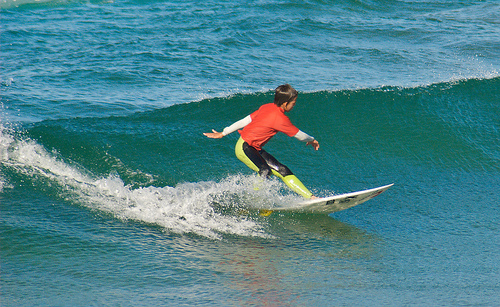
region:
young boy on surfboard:
[208, 63, 330, 215]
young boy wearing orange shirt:
[188, 62, 332, 211]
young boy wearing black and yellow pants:
[191, 67, 328, 209]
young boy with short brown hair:
[191, 60, 334, 212]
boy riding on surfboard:
[184, 67, 399, 222]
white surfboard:
[215, 177, 411, 214]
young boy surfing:
[167, 63, 409, 218]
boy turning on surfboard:
[187, 73, 406, 223]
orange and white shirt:
[221, 90, 311, 155]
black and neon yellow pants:
[228, 133, 323, 211]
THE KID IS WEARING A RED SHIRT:
[241, 97, 308, 157]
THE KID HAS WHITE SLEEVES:
[220, 110, 314, 151]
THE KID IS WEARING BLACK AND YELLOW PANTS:
[217, 135, 333, 205]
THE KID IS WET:
[190, 64, 351, 204]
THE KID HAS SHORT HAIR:
[271, 76, 297, 116]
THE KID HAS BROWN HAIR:
[268, 80, 300, 111]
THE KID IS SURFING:
[195, 80, 336, 212]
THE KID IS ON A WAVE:
[15, 66, 497, 221]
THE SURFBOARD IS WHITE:
[256, 178, 396, 222]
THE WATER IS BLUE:
[1, 1, 498, 302]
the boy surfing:
[202, 71, 327, 200]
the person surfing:
[205, 75, 326, 200]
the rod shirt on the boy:
[237, 104, 293, 150]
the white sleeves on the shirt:
[215, 114, 250, 137]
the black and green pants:
[229, 132, 324, 203]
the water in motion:
[12, 131, 241, 239]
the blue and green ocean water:
[397, 99, 497, 284]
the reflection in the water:
[217, 237, 291, 304]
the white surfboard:
[252, 175, 395, 219]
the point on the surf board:
[366, 179, 400, 195]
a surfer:
[204, 73, 399, 240]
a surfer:
[240, 105, 352, 227]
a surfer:
[253, 90, 304, 152]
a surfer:
[231, 48, 348, 300]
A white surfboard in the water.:
[247, 177, 392, 219]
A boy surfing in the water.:
[210, 55, 355, 211]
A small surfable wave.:
[35, 60, 485, 150]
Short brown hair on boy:
[260, 73, 324, 130]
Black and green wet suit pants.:
[194, 76, 372, 233]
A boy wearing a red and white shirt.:
[156, 74, 369, 229]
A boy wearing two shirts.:
[193, 66, 340, 212]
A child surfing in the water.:
[145, 57, 409, 270]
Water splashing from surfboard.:
[102, 41, 313, 305]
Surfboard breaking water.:
[137, 145, 349, 236]